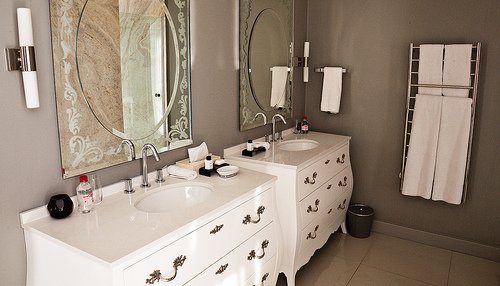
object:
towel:
[442, 44, 472, 97]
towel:
[432, 94, 473, 207]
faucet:
[140, 143, 161, 187]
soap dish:
[217, 165, 239, 178]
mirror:
[50, 0, 194, 177]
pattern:
[46, 0, 105, 179]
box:
[176, 153, 222, 176]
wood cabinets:
[389, 33, 479, 211]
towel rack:
[399, 38, 480, 207]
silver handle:
[143, 254, 186, 284]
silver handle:
[244, 239, 270, 262]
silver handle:
[242, 205, 266, 225]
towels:
[398, 94, 445, 200]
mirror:
[236, 1, 294, 132]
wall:
[1, 1, 308, 284]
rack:
[399, 42, 482, 204]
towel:
[320, 67, 341, 114]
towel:
[416, 44, 443, 96]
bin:
[347, 203, 374, 238]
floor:
[290, 227, 499, 286]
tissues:
[188, 140, 208, 161]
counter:
[78, 213, 152, 250]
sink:
[132, 181, 215, 214]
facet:
[272, 114, 288, 143]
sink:
[276, 139, 319, 151]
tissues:
[167, 140, 234, 180]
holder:
[314, 66, 346, 73]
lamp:
[15, 6, 42, 109]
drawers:
[118, 190, 277, 286]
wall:
[303, 2, 483, 254]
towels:
[403, 41, 474, 199]